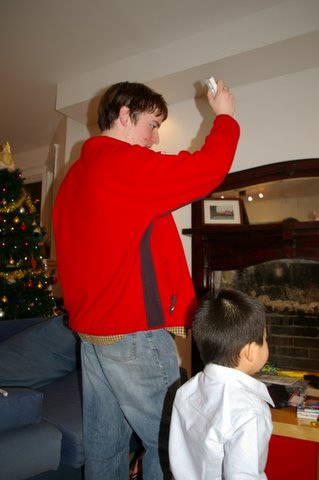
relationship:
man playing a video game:
[51, 80, 240, 480] [202, 42, 318, 414]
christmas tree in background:
[0, 140, 62, 319] [2, 34, 75, 474]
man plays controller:
[51, 80, 240, 480] [205, 76, 216, 96]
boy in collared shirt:
[168, 288, 276, 479] [167, 359, 280, 478]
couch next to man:
[2, 301, 99, 477] [38, 71, 237, 260]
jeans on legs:
[71, 314, 190, 473] [72, 299, 188, 479]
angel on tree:
[2, 142, 14, 171] [1, 168, 48, 316]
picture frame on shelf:
[199, 196, 244, 224] [181, 222, 318, 233]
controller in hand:
[205, 76, 216, 96] [205, 81, 236, 115]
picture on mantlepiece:
[202, 195, 243, 227] [180, 216, 317, 251]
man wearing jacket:
[51, 80, 240, 480] [51, 112, 241, 333]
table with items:
[212, 303, 314, 479] [291, 392, 307, 415]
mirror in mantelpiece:
[236, 175, 318, 226] [191, 158, 308, 225]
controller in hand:
[205, 76, 216, 96] [206, 80, 233, 120]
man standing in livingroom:
[72, 80, 258, 268] [14, 105, 63, 478]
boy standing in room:
[165, 288, 276, 479] [0, 0, 318, 478]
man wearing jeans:
[51, 80, 240, 480] [78, 329, 180, 477]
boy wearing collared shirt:
[165, 288, 276, 479] [167, 359, 280, 478]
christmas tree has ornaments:
[0, 140, 62, 319] [10, 228, 26, 251]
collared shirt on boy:
[167, 359, 280, 478] [168, 288, 276, 479]